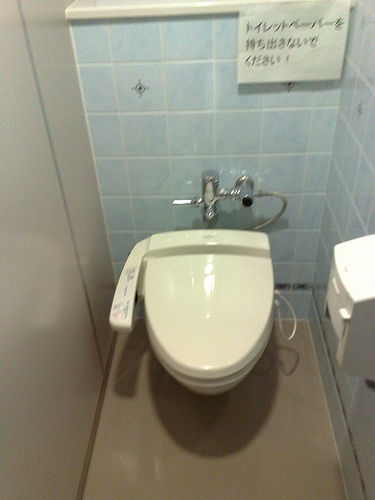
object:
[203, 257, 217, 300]
light reflection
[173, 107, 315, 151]
tile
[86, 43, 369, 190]
wall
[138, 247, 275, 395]
seat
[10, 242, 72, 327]
reflection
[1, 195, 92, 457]
wall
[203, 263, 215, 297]
light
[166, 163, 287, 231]
metal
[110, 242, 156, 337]
controls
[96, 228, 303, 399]
toilet side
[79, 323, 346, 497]
floor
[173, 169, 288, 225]
silverware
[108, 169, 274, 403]
toilet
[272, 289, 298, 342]
cord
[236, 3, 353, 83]
paper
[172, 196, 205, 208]
flusher handle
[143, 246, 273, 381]
lid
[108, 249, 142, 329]
armrest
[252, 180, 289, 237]
pipe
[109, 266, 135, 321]
markings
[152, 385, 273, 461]
shadow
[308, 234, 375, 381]
container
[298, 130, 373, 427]
wall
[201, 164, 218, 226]
pipe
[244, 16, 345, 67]
writing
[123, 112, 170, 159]
tile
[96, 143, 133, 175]
grout